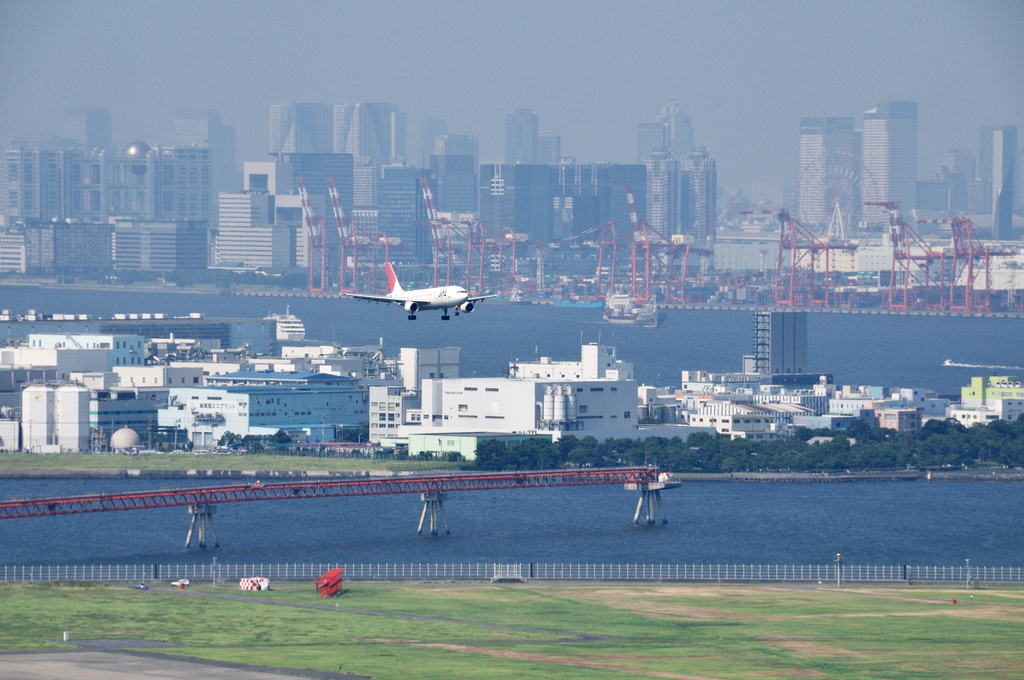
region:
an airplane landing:
[346, 264, 498, 319]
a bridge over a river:
[0, 456, 661, 534]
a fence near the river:
[0, 557, 1016, 583]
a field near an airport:
[0, 582, 1023, 674]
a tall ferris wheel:
[795, 154, 882, 244]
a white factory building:
[417, 347, 634, 452]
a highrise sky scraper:
[865, 94, 917, 227]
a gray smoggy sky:
[2, 0, 1021, 217]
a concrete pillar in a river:
[183, 502, 222, 553]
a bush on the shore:
[470, 437, 510, 469]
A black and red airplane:
[355, 253, 501, 329]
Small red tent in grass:
[307, 558, 346, 594]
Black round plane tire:
[437, 308, 454, 324]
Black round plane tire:
[406, 310, 422, 324]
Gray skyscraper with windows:
[758, 303, 815, 376]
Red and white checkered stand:
[233, 572, 273, 593]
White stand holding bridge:
[618, 475, 685, 527]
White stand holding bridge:
[412, 490, 464, 541]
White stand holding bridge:
[181, 506, 230, 554]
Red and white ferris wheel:
[792, 150, 890, 240]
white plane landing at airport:
[362, 244, 487, 349]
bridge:
[2, 420, 721, 522]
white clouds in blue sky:
[26, 25, 99, 57]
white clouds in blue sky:
[702, 40, 766, 78]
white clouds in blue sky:
[845, 31, 912, 71]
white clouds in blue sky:
[307, 10, 438, 88]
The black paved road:
[10, 623, 331, 677]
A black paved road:
[3, 603, 301, 677]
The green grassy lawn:
[0, 559, 1015, 677]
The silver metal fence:
[13, 537, 1017, 602]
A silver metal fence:
[3, 549, 1022, 597]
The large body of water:
[10, 452, 1022, 590]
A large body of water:
[0, 459, 1023, 595]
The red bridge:
[9, 452, 692, 510]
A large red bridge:
[3, 451, 708, 513]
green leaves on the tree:
[620, 437, 655, 469]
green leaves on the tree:
[547, 423, 564, 455]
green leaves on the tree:
[520, 414, 531, 478]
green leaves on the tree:
[596, 440, 619, 483]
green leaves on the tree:
[684, 426, 710, 499]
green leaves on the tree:
[924, 417, 938, 434]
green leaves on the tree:
[983, 423, 994, 469]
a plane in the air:
[374, 218, 458, 390]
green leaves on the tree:
[787, 449, 804, 495]